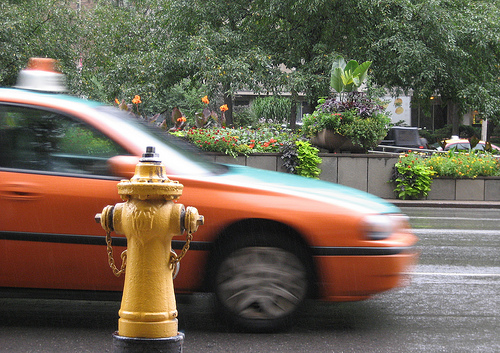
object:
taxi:
[0, 56, 418, 330]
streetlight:
[359, 214, 393, 241]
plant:
[392, 150, 433, 200]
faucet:
[92, 205, 116, 234]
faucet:
[182, 205, 205, 234]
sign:
[13, 56, 70, 95]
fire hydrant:
[93, 146, 208, 352]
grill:
[216, 246, 303, 318]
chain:
[103, 235, 126, 278]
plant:
[302, 60, 390, 153]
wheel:
[209, 222, 317, 332]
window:
[0, 101, 133, 180]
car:
[0, 55, 418, 333]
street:
[0, 205, 500, 351]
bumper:
[0, 230, 403, 257]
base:
[110, 330, 186, 352]